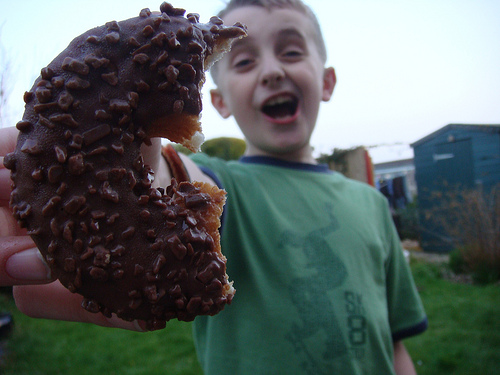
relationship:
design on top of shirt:
[273, 199, 352, 374] [178, 144, 430, 375]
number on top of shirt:
[344, 313, 370, 349] [178, 144, 430, 375]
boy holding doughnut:
[1, 2, 433, 375] [0, 0, 254, 333]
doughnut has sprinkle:
[0, 0, 254, 333] [130, 51, 151, 66]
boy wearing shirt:
[1, 2, 433, 375] [178, 144, 430, 375]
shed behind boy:
[406, 118, 499, 256] [1, 2, 433, 375]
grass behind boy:
[400, 255, 499, 374] [1, 2, 433, 375]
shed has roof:
[406, 118, 499, 256] [406, 117, 499, 149]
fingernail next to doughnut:
[7, 244, 52, 286] [0, 0, 254, 333]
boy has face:
[1, 2, 433, 375] [221, 12, 325, 158]